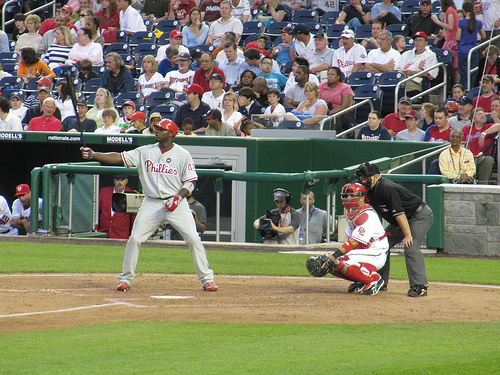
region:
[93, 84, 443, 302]
men playing baseball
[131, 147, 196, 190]
man plays for phillies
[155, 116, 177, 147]
baseball player in red helmet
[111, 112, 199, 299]
baseball player in white uniform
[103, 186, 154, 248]
television camera is behind the player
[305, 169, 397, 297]
catcher has a black glove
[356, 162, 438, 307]
umpire is behind the catcher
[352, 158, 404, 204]
umpire wears a black mask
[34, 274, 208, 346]
white lines are on the ground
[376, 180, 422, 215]
umpire wearing a black shirt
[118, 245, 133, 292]
right leg of a man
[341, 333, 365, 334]
section of a lawn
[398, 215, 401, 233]
arm of a man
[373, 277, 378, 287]
shoe of a man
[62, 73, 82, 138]
a black base ball bat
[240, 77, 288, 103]
section of onlookers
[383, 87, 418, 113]
group of people looking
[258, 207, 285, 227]
part of a camera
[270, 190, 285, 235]
a camera man standing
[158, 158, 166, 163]
part of a jersey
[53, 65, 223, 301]
Man is playing baseball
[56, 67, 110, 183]
Man holding a black bat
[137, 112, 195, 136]
Man wearing a red helmet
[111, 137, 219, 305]
Man wearing white uniform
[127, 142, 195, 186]
Man's ball team is Phillies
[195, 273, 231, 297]
Man wearing a red shoe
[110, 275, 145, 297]
Man wearing red shoe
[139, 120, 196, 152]
Man has dark skin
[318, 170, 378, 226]
Man wearing red catchers helmet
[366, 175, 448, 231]
Man wearing black T shirt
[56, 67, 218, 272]
the man is holding a bat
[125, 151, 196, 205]
the shirt says Phillies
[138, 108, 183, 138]
the man's helmet is red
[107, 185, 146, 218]
the camera is recording the game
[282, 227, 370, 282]
the man is wearing a baseball glove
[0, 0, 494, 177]
fans are watching the game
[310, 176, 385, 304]
the man is squatting down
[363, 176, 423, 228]
the man's shirt is black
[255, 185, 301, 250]
the man is recording the game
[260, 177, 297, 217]
the man is wearing headphones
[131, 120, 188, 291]
baseball player holding a bat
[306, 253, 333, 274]
baseball catcher's mitt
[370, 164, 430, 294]
baseball umpire wearing black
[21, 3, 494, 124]
fans sitting in a baseball stadium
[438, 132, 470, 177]
man with a yellow longsleeved shirt and a red lanyard around his neck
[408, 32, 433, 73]
man wearing a white shirt and a red baseball cap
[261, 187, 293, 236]
man wearing earphones holding a camera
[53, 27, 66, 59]
woman wearing a blue and white striped shirt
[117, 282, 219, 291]
two red baseball shoes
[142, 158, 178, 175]
Phillies logo on the batter's shirt